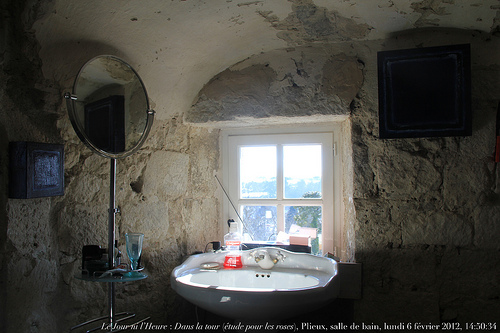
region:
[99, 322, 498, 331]
photo tag on the picture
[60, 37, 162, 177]
mirror in the bathroom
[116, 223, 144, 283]
glass on a shelf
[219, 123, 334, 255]
window in the bathroom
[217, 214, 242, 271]
bottle on the sink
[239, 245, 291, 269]
faucet and handles on the sink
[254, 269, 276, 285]
three holes in the sink basin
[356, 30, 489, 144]
box on the wall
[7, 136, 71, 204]
small box on the wall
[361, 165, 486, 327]
cement block wall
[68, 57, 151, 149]
Circular mirror on pole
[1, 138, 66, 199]
Box fixed on wall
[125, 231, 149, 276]
Blue glass on stand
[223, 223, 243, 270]
Bottle of liquid soap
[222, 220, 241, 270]
Soap bottle on sink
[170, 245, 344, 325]
White sink beside window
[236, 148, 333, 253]
Window with four panes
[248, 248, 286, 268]
White and silver faucet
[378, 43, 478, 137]
Television on a wall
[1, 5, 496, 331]
Wall made of stones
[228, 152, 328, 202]
Lights through the photo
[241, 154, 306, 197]
Glass panes on the window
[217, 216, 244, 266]
A bottle in the photo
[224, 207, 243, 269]
A plastic bottle in the photo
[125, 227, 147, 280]
A glass in the photo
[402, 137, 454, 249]
A stone wall in the photo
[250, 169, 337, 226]
Trees in the photo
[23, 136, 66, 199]
A cabinet in the photo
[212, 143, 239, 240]
Window frame on the wall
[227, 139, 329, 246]
Glass window in the photo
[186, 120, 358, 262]
window on the wall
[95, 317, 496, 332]
words on bottom of photo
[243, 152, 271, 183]
light outside the window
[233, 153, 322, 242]
four glasses on the window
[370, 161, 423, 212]
wall next to the window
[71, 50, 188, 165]
mirror in the room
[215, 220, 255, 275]
item next to sink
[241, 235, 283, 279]
faucet of the sink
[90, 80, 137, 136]
reflection of an object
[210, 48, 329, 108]
wall above the window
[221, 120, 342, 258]
small white painted wooden window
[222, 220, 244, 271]
bottle of red mouthwash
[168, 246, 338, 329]
white ceramic pedestal sink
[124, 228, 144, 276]
pale blue clear glass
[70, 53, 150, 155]
large round mirror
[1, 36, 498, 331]
raw cement and stone walls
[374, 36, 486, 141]
large black stereo speaker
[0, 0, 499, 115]
rounded cement ceiling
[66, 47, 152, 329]
silver metal toiletry stand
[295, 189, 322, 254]
tree outside the window